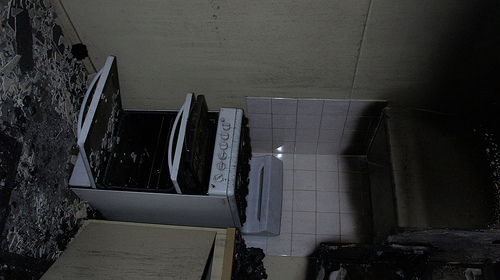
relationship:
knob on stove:
[212, 172, 223, 183] [67, 52, 284, 236]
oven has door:
[62, 70, 273, 232] [74, 55, 130, 192]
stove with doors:
[85, 70, 234, 207] [199, 191, 286, 231]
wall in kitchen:
[242, 100, 409, 262] [0, 4, 499, 276]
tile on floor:
[314, 169, 339, 191] [5, 4, 94, 274]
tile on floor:
[316, 190, 338, 210] [5, 4, 94, 274]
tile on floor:
[292, 169, 315, 188] [5, 4, 94, 274]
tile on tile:
[291, 188, 321, 211] [290, 233, 316, 255]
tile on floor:
[290, 233, 316, 255] [5, 4, 94, 274]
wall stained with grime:
[0, 2, 498, 154] [53, 0, 478, 101]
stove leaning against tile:
[58, 59, 294, 206] [2, 3, 99, 275]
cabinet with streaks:
[21, 192, 241, 278] [50, 241, 221, 279]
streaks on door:
[50, 241, 221, 279] [30, 215, 219, 278]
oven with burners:
[77, 72, 279, 221] [236, 122, 263, 212]